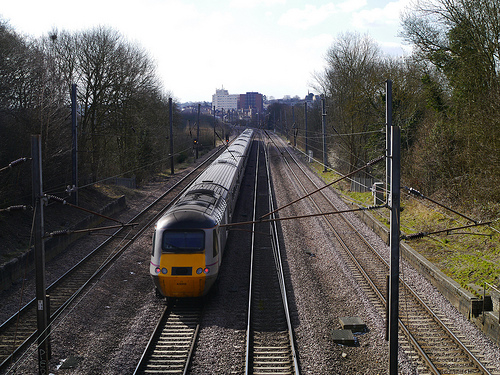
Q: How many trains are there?
A: One.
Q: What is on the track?
A: A train.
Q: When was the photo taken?
A: Daytime.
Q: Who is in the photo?
A: Nobody.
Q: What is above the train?
A: Wires.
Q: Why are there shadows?
A: It is daytime.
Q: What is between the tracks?
A: Pebbles.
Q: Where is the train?
A: On the track.